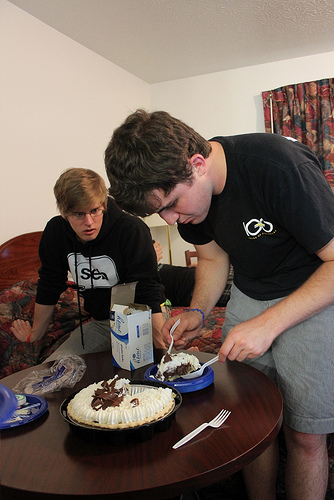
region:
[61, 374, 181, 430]
chocolate cream pie on table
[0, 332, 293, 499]
brown wooden table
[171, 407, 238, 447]
plastic fork on round table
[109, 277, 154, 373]
box of plastic forks is open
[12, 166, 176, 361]
person looking at pie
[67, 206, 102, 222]
person wearing glasses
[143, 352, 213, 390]
slice of pie on top of a stack of blue paper plates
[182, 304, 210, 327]
blue bracelet on wrist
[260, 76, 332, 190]
curtains behind man holding pie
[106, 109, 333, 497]
man using two forks to serve a slice of chocolate cream pie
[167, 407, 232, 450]
WHITE PLASTIC FORK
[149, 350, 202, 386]
SLICE OF CHOCOLATE CREAM PIE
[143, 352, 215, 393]
SLICE OF CHOCOLATE PIE ON A BLUE PLATE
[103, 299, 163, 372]
BOX OF PLASTIC FORKS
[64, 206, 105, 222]
A PAIR OF GLASSES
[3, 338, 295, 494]
A ROUND WOODEN TABLE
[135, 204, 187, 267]
A LAMP IN THE BACKGROUND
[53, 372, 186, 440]
CHOCOLATE PIE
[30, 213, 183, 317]
A BLACK AND WHITE SHIRT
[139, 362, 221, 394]
A STACK OF BLUE PLASTIC PLATES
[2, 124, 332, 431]
two boys in a room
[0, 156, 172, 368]
boy wearing glasses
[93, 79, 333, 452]
boy cutting cake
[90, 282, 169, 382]
box of plastic forks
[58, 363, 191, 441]
cream pie on the table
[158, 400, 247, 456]
white plastic fork on the table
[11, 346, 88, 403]
plastic bags on table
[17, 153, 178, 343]
boy wearing black hoodie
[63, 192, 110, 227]
boy wearing glasses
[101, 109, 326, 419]
Young man cutting chocolate pie.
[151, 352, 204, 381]
Chocolate pie on blue plate.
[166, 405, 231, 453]
White plastic fork on table.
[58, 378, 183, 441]
Chocolate pie with white whipped cream in black container.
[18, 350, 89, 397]
Plastic bag sitting on table.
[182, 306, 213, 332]
Blue band around young man's wrist.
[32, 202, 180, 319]
Young wearing black and white jacket.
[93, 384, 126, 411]
Chocolate curls on top of pie.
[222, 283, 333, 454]
Young man wearing gray shorts.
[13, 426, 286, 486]
Edge of brown coffee table.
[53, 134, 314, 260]
two boys are seen.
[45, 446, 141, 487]
table is brown in color.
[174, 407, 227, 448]
fork is white in color.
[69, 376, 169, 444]
cake is in black bowl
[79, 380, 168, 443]
cake is white in color.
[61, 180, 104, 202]
hair is blonde.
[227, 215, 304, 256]
boy is wearing black shirt.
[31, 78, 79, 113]
wall is white color.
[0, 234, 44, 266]
cot is brown in color.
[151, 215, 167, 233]
lamp is white in color.